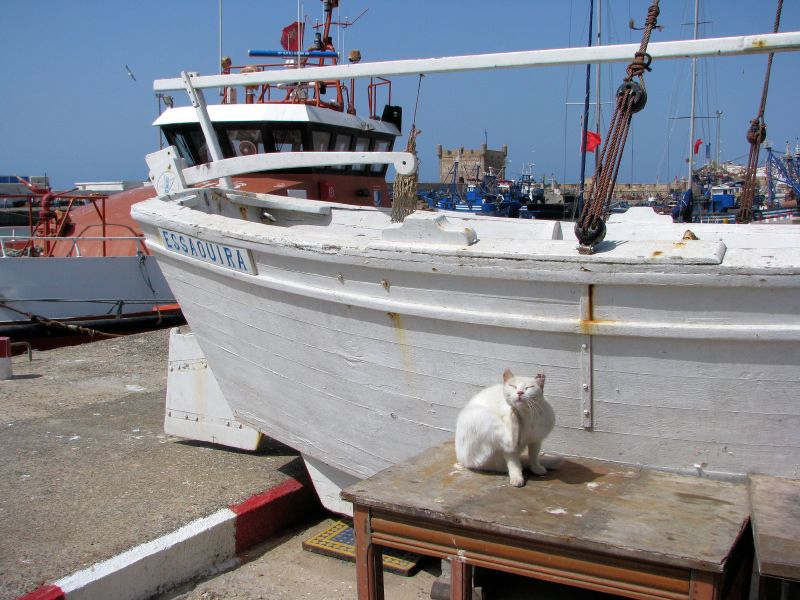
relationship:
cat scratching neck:
[451, 367, 555, 477] [502, 369, 547, 413]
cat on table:
[452, 346, 589, 496] [340, 432, 782, 593]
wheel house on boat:
[156, 105, 387, 179] [132, 20, 797, 577]